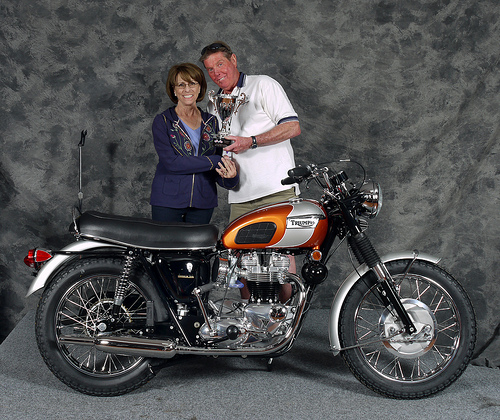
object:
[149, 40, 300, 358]
people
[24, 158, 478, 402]
motorcycle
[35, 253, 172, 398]
wheel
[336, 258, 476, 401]
wheel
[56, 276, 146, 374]
spokes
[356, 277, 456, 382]
spokes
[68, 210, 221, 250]
seat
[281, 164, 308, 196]
handles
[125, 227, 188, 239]
leather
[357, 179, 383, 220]
light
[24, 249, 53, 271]
light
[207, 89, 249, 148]
trophy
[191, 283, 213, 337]
pedal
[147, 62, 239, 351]
woman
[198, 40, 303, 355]
man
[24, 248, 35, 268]
brake light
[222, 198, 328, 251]
gas tank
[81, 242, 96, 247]
silver, and black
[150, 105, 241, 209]
blue jacket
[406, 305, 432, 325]
chrome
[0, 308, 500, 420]
gray carpet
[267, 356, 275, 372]
chrome kickstand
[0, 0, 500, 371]
gray backdrop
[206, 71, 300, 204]
white shirt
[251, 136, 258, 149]
black watch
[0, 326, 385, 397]
shadow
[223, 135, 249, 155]
left hand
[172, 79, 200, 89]
glasses